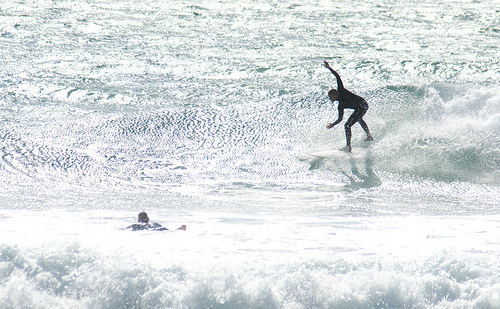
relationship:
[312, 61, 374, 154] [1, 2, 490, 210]
man on water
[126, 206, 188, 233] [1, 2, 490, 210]
person in water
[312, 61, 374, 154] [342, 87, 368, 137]
man wears wetsuit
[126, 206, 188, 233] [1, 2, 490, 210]
person on water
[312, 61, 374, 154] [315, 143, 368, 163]
man on surfboard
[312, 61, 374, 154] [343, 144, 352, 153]
man has foot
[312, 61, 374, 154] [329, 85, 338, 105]
man has head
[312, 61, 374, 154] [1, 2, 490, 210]
man in water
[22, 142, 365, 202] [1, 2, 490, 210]
ripples in water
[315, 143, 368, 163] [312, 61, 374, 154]
surfboard supports man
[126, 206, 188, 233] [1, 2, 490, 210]
person lying on water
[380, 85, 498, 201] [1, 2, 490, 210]
wave in water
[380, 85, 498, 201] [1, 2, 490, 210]
wave behind water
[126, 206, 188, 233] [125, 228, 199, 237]
person lying on surfboard